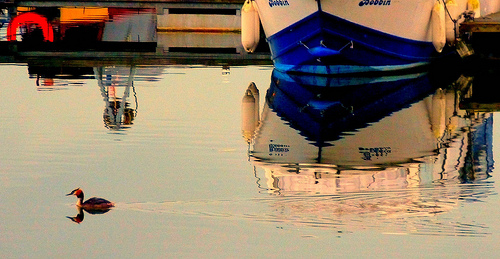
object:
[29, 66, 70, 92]
reflection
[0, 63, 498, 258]
water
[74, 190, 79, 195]
red spot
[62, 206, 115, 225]
reflection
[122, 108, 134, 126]
girl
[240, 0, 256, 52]
bouy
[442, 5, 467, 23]
rope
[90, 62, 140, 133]
reflection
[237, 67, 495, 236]
reflection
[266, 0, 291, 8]
wording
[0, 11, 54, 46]
lifesaver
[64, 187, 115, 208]
bird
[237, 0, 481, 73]
boat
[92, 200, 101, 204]
feathers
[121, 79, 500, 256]
surface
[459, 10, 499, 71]
pier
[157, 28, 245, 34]
stripe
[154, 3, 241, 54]
structure